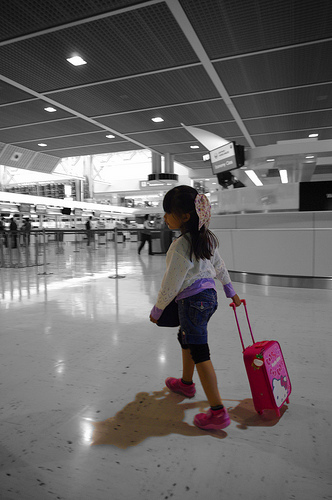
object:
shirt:
[152, 229, 231, 313]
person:
[7, 214, 18, 250]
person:
[84, 215, 93, 246]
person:
[22, 217, 31, 249]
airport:
[0, 2, 331, 499]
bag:
[227, 298, 293, 423]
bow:
[193, 189, 213, 234]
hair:
[161, 184, 218, 266]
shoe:
[165, 374, 196, 399]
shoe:
[191, 406, 229, 432]